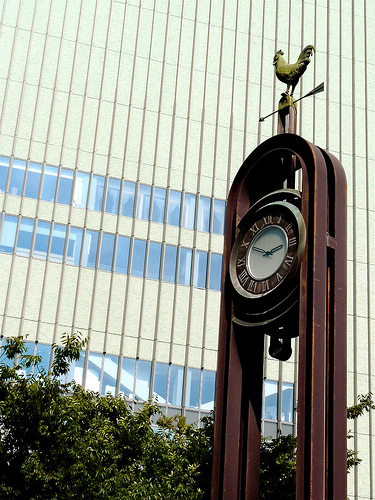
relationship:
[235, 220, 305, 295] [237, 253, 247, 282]
clock has numbers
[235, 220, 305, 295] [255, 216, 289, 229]
clock has numbers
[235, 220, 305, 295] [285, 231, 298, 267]
clock has numbers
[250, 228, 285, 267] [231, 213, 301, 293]
time on clock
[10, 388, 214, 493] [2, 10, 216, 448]
tree in front of building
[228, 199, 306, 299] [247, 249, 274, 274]
clock with interior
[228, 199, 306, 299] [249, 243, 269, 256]
clock has hand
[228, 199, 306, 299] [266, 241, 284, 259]
clock has hand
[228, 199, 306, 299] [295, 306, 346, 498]
clock standing on pillar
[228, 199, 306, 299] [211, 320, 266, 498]
clock standing on pillar